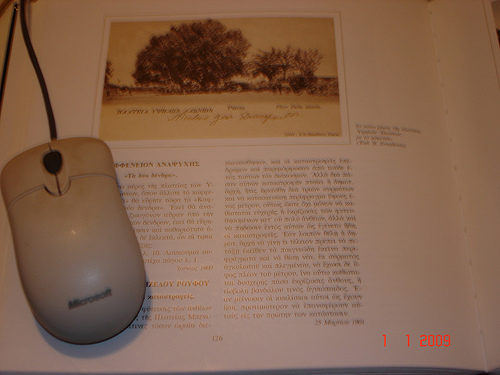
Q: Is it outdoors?
A: Yes, it is outdoors.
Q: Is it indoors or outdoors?
A: It is outdoors.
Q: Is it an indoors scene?
A: No, it is outdoors.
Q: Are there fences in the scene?
A: No, there are no fences.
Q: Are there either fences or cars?
A: No, there are no fences or cars.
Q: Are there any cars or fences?
A: No, there are no fences or cars.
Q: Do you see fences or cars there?
A: No, there are no fences or cars.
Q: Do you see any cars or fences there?
A: No, there are no fences or cars.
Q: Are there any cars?
A: No, there are no cars.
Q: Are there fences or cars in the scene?
A: No, there are no cars or fences.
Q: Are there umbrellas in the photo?
A: No, there are no umbrellas.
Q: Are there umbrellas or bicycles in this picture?
A: No, there are no umbrellas or bicycles.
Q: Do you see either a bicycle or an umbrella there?
A: No, there are no umbrellas or bicycles.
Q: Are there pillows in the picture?
A: No, there are no pillows.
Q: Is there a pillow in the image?
A: No, there are no pillows.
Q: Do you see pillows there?
A: No, there are no pillows.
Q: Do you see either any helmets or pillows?
A: No, there are no pillows or helmets.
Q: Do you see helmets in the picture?
A: No, there are no helmets.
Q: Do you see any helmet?
A: No, there are no helmets.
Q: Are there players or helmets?
A: No, there are no helmets or players.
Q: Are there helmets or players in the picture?
A: No, there are no helmets or players.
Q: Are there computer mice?
A: Yes, there is a computer mouse.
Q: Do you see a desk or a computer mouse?
A: Yes, there is a computer mouse.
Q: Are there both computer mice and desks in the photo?
A: No, there is a computer mouse but no desks.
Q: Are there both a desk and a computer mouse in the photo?
A: No, there is a computer mouse but no desks.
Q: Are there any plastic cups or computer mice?
A: Yes, there is a plastic computer mouse.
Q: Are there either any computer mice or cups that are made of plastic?
A: Yes, the computer mouse is made of plastic.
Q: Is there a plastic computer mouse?
A: Yes, there is a computer mouse that is made of plastic.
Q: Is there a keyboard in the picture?
A: No, there are no keyboards.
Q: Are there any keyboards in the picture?
A: No, there are no keyboards.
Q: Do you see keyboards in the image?
A: No, there are no keyboards.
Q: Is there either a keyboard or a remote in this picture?
A: No, there are no keyboards or remote controls.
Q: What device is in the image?
A: The device is a computer mouse.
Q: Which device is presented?
A: The device is a computer mouse.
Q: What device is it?
A: The device is a computer mouse.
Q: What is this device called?
A: This is a computer mouse.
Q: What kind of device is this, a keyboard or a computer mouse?
A: This is a computer mouse.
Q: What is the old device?
A: The device is a computer mouse.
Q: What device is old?
A: The device is a computer mouse.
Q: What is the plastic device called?
A: The device is a computer mouse.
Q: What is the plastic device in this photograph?
A: The device is a computer mouse.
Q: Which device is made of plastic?
A: The device is a computer mouse.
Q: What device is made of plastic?
A: The device is a computer mouse.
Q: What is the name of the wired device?
A: The device is a computer mouse.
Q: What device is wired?
A: The device is a computer mouse.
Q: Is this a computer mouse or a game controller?
A: This is a computer mouse.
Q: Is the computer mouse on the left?
A: Yes, the computer mouse is on the left of the image.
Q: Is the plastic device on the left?
A: Yes, the computer mouse is on the left of the image.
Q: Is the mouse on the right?
A: No, the mouse is on the left of the image.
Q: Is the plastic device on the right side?
A: No, the mouse is on the left of the image.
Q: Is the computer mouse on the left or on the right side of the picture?
A: The computer mouse is on the left of the image.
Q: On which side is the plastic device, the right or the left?
A: The computer mouse is on the left of the image.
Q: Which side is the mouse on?
A: The mouse is on the left of the image.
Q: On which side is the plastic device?
A: The mouse is on the left of the image.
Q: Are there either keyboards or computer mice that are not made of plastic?
A: No, there is a computer mouse but it is made of plastic.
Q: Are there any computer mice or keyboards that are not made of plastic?
A: No, there is a computer mouse but it is made of plastic.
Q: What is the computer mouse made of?
A: The computer mouse is made of plastic.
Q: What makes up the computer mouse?
A: The computer mouse is made of plastic.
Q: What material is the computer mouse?
A: The computer mouse is made of plastic.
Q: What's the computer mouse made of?
A: The computer mouse is made of plastic.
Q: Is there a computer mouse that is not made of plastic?
A: No, there is a computer mouse but it is made of plastic.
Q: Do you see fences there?
A: No, there are no fences.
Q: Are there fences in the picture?
A: No, there are no fences.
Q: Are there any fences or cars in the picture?
A: No, there are no fences or cars.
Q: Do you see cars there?
A: No, there are no cars.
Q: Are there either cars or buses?
A: No, there are no cars or buses.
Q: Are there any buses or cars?
A: No, there are no cars or buses.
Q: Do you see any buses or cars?
A: No, there are no cars or buses.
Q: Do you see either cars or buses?
A: No, there are no cars or buses.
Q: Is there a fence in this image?
A: No, there are no fences.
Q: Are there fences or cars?
A: No, there are no fences or cars.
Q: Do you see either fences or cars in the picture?
A: No, there are no fences or cars.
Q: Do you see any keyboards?
A: No, there are no keyboards.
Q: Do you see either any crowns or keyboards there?
A: No, there are no keyboards or crowns.